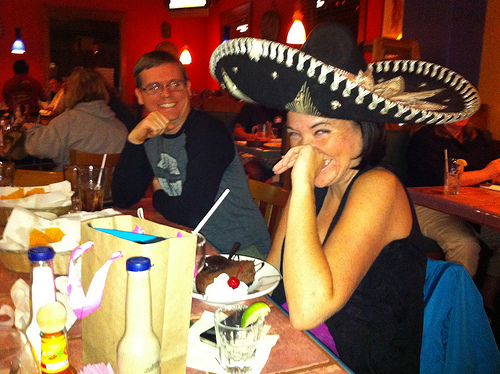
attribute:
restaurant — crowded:
[1, 2, 499, 373]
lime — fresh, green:
[240, 302, 270, 326]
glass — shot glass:
[214, 304, 265, 374]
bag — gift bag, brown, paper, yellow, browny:
[81, 215, 197, 373]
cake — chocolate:
[196, 258, 256, 294]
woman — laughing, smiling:
[264, 110, 426, 373]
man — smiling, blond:
[110, 51, 272, 261]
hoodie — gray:
[23, 100, 127, 170]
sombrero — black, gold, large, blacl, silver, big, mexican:
[209, 21, 481, 123]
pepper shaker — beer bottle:
[118, 256, 162, 373]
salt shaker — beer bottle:
[27, 247, 57, 363]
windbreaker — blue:
[424, 259, 499, 373]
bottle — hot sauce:
[36, 302, 77, 374]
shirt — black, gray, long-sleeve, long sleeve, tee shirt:
[110, 108, 271, 255]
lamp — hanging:
[11, 4, 27, 55]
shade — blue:
[12, 39, 25, 54]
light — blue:
[221, 38, 227, 42]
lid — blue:
[126, 257, 151, 270]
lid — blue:
[28, 247, 55, 260]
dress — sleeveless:
[322, 167, 423, 373]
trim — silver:
[208, 36, 480, 126]